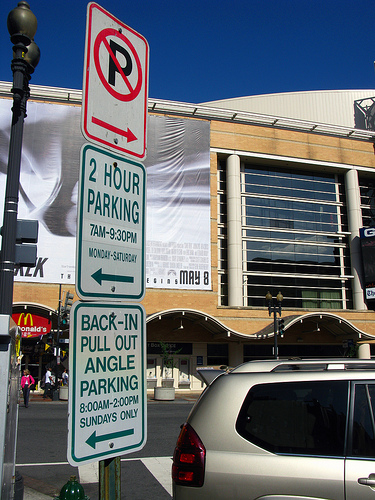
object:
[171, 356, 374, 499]
car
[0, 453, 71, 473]
lines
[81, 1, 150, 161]
board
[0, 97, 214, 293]
banner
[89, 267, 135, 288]
arrow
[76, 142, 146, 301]
sign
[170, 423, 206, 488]
light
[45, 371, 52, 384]
t-shirt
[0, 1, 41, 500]
lamppost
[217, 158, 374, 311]
windows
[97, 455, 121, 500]
post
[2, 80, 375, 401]
building